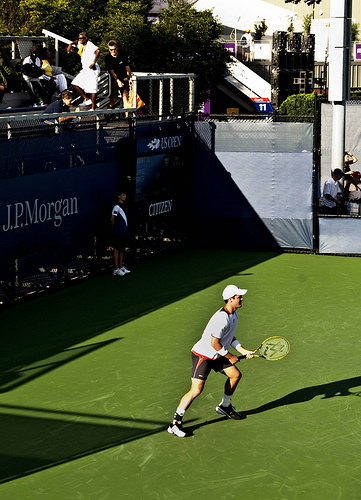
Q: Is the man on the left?
A: Yes, the man is on the left of the image.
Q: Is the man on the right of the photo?
A: No, the man is on the left of the image.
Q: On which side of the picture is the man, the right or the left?
A: The man is on the left of the image.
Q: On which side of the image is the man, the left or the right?
A: The man is on the left of the image.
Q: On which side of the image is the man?
A: The man is on the left of the image.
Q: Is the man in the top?
A: Yes, the man is in the top of the image.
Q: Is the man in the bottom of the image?
A: No, the man is in the top of the image.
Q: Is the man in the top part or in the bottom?
A: The man is in the top of the image.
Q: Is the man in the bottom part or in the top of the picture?
A: The man is in the top of the image.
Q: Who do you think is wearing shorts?
A: The man is wearing shorts.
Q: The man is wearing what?
A: The man is wearing shorts.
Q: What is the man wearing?
A: The man is wearing shorts.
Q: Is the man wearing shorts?
A: Yes, the man is wearing shorts.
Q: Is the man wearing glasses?
A: No, the man is wearing shorts.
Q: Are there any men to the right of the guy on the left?
A: Yes, there is a man to the right of the guy.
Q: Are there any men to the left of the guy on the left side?
A: No, the man is to the right of the guy.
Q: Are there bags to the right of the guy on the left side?
A: No, there is a man to the right of the guy.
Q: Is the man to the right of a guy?
A: Yes, the man is to the right of a guy.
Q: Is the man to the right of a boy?
A: No, the man is to the right of a guy.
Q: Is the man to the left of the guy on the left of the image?
A: No, the man is to the right of the guy.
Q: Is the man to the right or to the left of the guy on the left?
A: The man is to the right of the guy.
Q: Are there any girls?
A: No, there are no girls.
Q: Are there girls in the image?
A: No, there are no girls.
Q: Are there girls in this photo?
A: No, there are no girls.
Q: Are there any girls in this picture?
A: No, there are no girls.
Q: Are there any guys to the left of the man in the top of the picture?
A: Yes, there is a guy to the left of the man.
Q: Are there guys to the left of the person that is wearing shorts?
A: Yes, there is a guy to the left of the man.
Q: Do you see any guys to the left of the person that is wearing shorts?
A: Yes, there is a guy to the left of the man.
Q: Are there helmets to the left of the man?
A: No, there is a guy to the left of the man.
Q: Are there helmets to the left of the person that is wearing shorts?
A: No, there is a guy to the left of the man.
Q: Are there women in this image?
A: No, there are no women.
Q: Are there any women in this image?
A: No, there are no women.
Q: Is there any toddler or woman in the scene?
A: No, there are no women or toddlers.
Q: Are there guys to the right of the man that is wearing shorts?
A: Yes, there is a guy to the right of the man.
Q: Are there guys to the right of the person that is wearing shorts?
A: Yes, there is a guy to the right of the man.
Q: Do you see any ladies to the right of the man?
A: No, there is a guy to the right of the man.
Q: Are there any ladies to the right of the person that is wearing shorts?
A: No, there is a guy to the right of the man.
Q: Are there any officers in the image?
A: No, there are no officers.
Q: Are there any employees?
A: No, there are no employees.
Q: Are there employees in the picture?
A: No, there are no employees.